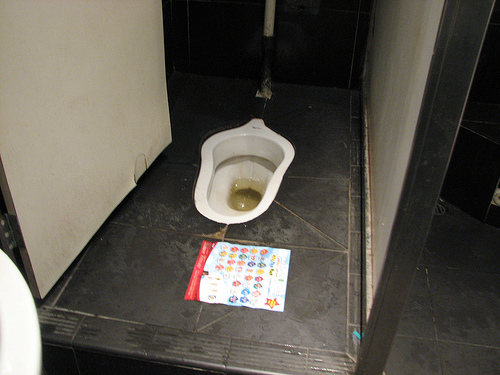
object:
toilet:
[188, 118, 297, 227]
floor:
[31, 233, 182, 374]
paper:
[182, 238, 293, 313]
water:
[228, 187, 259, 214]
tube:
[249, 4, 279, 116]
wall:
[361, 3, 417, 171]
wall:
[169, 3, 371, 91]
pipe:
[260, 7, 277, 95]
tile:
[292, 97, 351, 184]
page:
[182, 240, 210, 299]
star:
[264, 297, 281, 309]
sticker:
[183, 238, 291, 314]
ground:
[35, 310, 364, 374]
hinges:
[12, 203, 38, 243]